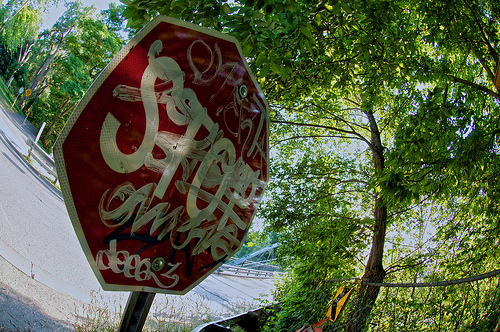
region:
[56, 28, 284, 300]
a vandalized stop sign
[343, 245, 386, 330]
a tree trunk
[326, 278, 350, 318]
a left arrow street sign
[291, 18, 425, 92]
a section of leaves in a tree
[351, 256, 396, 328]
a section of a tree trunk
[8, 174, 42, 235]
a section of a road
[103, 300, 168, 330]
the sign pole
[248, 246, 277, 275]
a section of a bridge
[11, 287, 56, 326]
part of a dirt path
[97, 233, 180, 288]
graffiti on a stop sign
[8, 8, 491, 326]
Fish eye lens distorted image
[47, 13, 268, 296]
Octagonal red stop sign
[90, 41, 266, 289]
stop sign covered in graffiti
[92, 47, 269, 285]
at least 5 taggers represented in graffiti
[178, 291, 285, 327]
right side of street guard rail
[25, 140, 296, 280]
left side of street guard rail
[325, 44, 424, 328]
Tall, fully leaved tree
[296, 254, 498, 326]
metal chain link fence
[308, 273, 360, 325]
left curve yellow sign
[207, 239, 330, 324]
bridge over small river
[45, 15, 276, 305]
The sign is red.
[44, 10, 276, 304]
The sign is octagon.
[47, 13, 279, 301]
Paint is covering the sign.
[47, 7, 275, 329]
Sign on a pole.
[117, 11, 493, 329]
the leaves are green.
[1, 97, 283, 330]
The street is concrete.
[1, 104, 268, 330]
The street is grey.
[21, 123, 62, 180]
the railing is metal.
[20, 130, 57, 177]
The railing is grey.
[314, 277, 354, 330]
The sign is orange.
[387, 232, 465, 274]
a thin branch on the tree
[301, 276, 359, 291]
a thin branch on the tree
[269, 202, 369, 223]
a thin branch on the tree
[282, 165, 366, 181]
a thin branch on the tree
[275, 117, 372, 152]
a thin branch on the tree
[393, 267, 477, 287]
a thin branch on the tree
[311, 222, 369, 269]
a thin branch on the tree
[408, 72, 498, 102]
a thin branch on the tree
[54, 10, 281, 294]
a scribbles sign post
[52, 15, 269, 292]
the signpost is red and white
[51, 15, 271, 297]
Stop sign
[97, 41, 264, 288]
White grease marker tags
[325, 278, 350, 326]
Leftward curve sign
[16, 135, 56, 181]
Guard rail on left side of street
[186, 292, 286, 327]
Metal guard rail on right side of street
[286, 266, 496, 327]
Chain link fence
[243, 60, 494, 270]
Beautiful sunny day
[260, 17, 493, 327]
Trees in full bloom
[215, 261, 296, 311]
Narrow bridge over water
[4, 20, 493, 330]
distortion due to fish eye lens